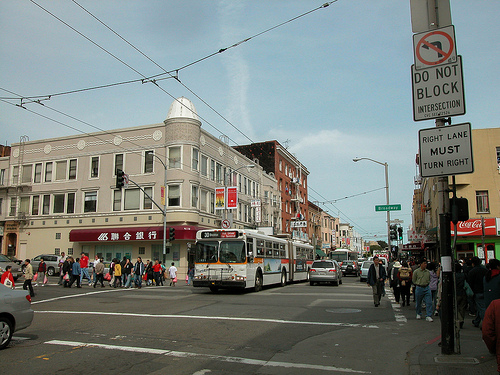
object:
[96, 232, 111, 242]
letter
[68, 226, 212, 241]
awning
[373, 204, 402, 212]
sign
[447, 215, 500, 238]
sign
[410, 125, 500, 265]
building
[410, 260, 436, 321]
man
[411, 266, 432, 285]
shirt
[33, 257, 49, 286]
woman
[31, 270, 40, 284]
bag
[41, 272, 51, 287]
bag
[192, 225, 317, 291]
bus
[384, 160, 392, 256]
pole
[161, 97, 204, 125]
dome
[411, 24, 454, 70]
sign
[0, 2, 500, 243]
sky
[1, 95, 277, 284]
building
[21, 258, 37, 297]
people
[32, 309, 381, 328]
lines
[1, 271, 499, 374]
street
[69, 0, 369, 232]
power lines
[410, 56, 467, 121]
sign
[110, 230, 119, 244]
letter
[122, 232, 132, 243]
letter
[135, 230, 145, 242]
letter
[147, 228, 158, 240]
letter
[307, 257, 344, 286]
car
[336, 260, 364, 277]
car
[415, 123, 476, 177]
signs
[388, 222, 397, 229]
streetlight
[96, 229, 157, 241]
writing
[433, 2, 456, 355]
pole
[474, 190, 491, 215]
window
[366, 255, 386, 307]
people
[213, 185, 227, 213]
sign